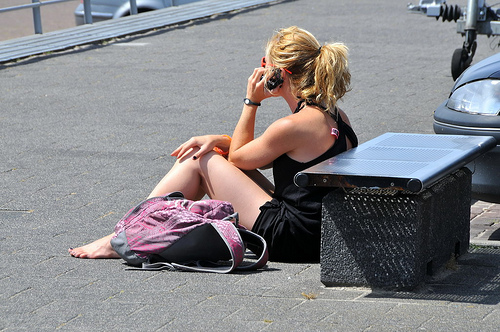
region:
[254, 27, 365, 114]
woman has brown hair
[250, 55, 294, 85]
woman has red glasses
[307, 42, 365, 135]
woman has hair in ponytail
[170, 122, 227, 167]
woman has black nail polish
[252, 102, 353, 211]
woman has black shirt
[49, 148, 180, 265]
woman has bare feet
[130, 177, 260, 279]
purple and grey backpack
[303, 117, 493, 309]
woman leans against grey bench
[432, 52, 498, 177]
blue car next to bench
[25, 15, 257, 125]
sidewalk is dark grey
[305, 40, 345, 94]
hair is in ponytail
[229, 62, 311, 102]
woman holds cell phone to ear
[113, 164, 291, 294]
purple backpack on ground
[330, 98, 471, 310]
black bench behind woman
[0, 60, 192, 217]
pavement is dark grey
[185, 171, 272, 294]
purple straps on backpack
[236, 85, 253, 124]
woman is wearing bracelet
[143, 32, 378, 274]
woman sits on pavement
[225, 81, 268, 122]
woman has balance bracelet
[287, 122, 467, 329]
bench is behind woman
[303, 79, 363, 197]
woman has black shirt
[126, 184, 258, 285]
purple backpack next to woman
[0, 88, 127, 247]
concrete is dark grey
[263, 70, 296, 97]
black phone in woman's ear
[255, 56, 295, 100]
woman wears red sunglasses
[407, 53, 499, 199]
dark blue car behind woman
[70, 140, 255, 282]
woman has bare feet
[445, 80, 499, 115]
the headlight of a car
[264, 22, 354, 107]
a woman's blonde hair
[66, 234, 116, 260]
a woman's barefoot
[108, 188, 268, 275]
a pink and gray backpack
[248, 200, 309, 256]
a woman's black shorts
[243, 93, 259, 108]
a woman's black wristwatch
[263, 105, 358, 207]
a woman's black tank top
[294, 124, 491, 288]
a concrete bench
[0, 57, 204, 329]
part of a tile walkway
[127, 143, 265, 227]
the leg of a woman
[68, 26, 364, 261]
woman talking on her cell phone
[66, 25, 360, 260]
blonde woman sitting against the bench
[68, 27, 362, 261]
blonde woman sitting on the concrete ground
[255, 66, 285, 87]
black cell phone in the hand of the woman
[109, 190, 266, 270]
pink and black backpack on the ground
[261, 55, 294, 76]
orange sunglasses on the woman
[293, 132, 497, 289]
concrete and metal bench on the ground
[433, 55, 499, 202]
front bumper of a black car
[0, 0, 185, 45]
gray metal guard rail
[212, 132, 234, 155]
orange bracelet on the woman